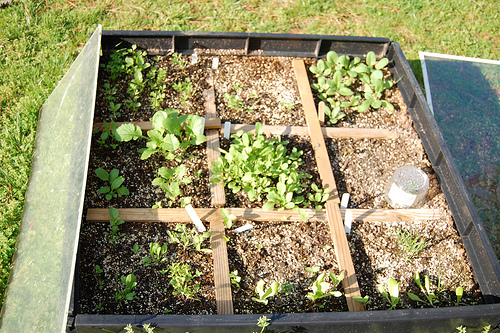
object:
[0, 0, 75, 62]
grass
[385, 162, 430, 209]
container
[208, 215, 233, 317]
bar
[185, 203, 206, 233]
label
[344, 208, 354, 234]
label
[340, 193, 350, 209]
label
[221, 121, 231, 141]
label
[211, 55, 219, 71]
label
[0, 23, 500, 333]
bed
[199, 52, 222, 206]
wood bar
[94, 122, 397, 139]
wood bar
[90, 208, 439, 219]
wood bar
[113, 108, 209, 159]
plant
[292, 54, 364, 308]
wood divider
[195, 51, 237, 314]
wood divider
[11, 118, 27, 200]
plant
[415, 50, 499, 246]
window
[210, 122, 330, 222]
plant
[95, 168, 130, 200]
plant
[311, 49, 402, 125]
plant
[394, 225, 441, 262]
plant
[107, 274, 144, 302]
vegetation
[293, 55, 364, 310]
bar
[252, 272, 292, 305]
plant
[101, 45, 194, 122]
plant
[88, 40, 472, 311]
farm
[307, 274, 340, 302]
plant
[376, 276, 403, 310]
plant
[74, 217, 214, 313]
section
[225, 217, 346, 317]
section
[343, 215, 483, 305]
section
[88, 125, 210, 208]
section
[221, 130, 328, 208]
section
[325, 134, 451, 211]
section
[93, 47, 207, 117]
section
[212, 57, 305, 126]
section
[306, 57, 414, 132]
section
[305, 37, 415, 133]
corner